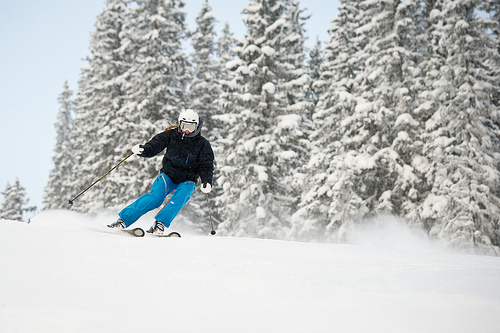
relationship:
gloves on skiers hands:
[127, 139, 212, 196] [194, 180, 213, 193]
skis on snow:
[66, 154, 231, 249] [129, 247, 341, 305]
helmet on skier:
[176, 109, 201, 129] [118, 78, 235, 240]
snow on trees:
[0, 207, 495, 330] [298, 10, 498, 256]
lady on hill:
[107, 109, 215, 237] [0, 206, 497, 331]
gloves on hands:
[131, 144, 144, 156] [116, 149, 216, 196]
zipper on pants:
[156, 166, 167, 195] [114, 169, 241, 246]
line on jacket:
[185, 152, 194, 171] [124, 115, 229, 197]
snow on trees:
[85, 23, 473, 190] [42, 6, 499, 252]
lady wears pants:
[107, 109, 215, 237] [117, 171, 194, 227]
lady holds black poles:
[107, 109, 215, 237] [68, 144, 216, 236]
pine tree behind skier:
[410, 0, 500, 252] [99, 106, 227, 226]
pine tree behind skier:
[226, 0, 311, 239] [99, 106, 227, 226]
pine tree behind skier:
[93, 0, 182, 216] [99, 106, 227, 226]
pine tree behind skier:
[41, 75, 73, 209] [99, 106, 227, 226]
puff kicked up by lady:
[31, 203, 203, 236] [107, 109, 215, 237]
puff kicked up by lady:
[347, 211, 462, 251] [107, 109, 215, 237]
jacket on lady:
[141, 127, 216, 184] [107, 109, 215, 237]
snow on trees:
[0, 207, 495, 330] [249, 47, 491, 209]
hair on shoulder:
[163, 121, 180, 132] [163, 127, 174, 139]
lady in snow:
[107, 109, 215, 237] [2, 208, 497, 331]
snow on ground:
[220, 242, 466, 321] [0, 210, 499, 330]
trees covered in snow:
[42, 6, 499, 252] [0, 232, 490, 327]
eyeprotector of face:
[177, 115, 199, 132] [174, 106, 202, 137]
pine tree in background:
[54, 75, 73, 209] [5, 11, 493, 257]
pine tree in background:
[93, 0, 118, 206] [5, 11, 493, 257]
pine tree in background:
[238, 4, 307, 220] [5, 11, 493, 257]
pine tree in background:
[428, 6, 498, 243] [5, 11, 493, 257]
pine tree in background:
[348, 6, 425, 236] [5, 11, 493, 257]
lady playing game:
[109, 76, 275, 258] [12, 83, 499, 326]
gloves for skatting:
[131, 144, 144, 156] [94, 110, 249, 252]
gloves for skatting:
[123, 134, 154, 163] [95, 106, 227, 246]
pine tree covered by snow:
[226, 0, 311, 239] [222, 15, 495, 255]